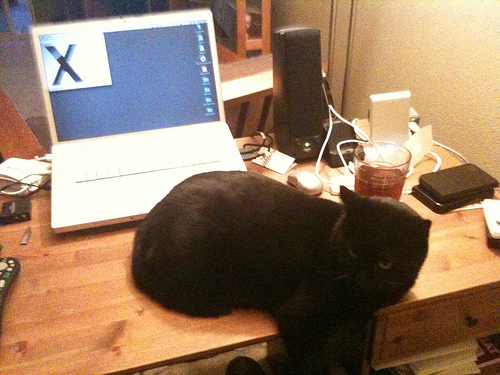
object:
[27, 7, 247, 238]
computer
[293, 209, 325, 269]
black hair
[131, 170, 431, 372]
cat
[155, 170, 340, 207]
back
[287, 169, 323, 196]
mouse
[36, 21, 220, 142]
screen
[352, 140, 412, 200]
glass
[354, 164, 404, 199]
liquid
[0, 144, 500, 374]
desk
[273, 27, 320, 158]
speaker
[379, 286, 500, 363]
drawer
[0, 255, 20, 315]
remote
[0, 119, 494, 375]
counter top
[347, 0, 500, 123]
wall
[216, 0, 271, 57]
shelf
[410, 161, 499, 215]
cell phone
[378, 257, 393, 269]
eye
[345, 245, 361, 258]
eye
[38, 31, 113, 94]
patch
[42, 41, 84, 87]
x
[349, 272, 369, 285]
nose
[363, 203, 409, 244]
hair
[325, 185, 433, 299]
cat head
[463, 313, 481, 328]
knob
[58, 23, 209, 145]
background